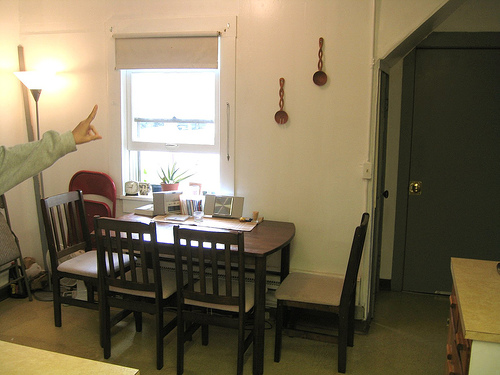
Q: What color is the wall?
A: White.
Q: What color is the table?
A: Brown.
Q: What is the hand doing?
A: Pointing.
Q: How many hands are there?
A: 1.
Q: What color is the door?
A: Green.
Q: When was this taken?
A: Daytime.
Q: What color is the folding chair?
A: Red.